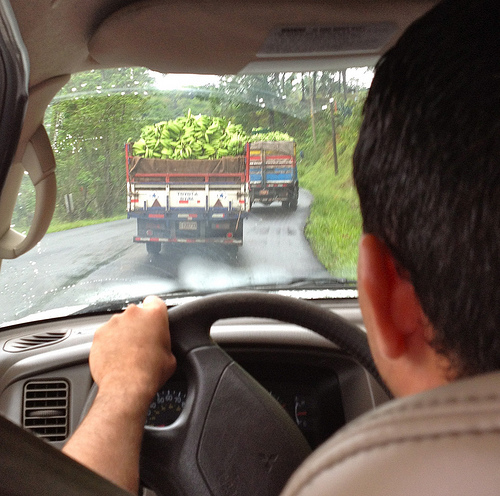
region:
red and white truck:
[119, 153, 282, 256]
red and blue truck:
[237, 130, 297, 185]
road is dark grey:
[240, 210, 285, 270]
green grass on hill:
[283, 151, 365, 268]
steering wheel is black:
[97, 270, 355, 493]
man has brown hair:
[355, 3, 490, 347]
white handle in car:
[0, 120, 75, 275]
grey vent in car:
[13, 365, 89, 452]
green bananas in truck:
[132, 105, 230, 174]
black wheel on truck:
[131, 212, 168, 262]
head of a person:
[328, 15, 499, 389]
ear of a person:
[354, 222, 425, 349]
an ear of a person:
[330, 230, 437, 360]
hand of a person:
[85, 275, 208, 387]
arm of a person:
[65, 385, 135, 482]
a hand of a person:
[85, 297, 194, 389]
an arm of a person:
[45, 398, 199, 486]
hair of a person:
[399, 95, 496, 216]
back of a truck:
[108, 207, 242, 264]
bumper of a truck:
[125, 219, 254, 261]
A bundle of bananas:
[134, 116, 241, 156]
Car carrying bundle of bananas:
[126, 115, 247, 256]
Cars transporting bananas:
[121, 111, 299, 258]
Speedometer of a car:
[136, 385, 189, 430]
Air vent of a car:
[21, 373, 76, 441]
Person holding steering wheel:
[61, 286, 393, 493]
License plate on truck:
[177, 223, 201, 233]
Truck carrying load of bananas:
[124, 113, 251, 253]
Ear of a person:
[353, 237, 415, 356]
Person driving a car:
[68, 25, 485, 491]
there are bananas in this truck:
[113, 104, 274, 261]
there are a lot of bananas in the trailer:
[120, 102, 260, 252]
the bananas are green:
[101, 68, 269, 251]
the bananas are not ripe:
[118, 85, 263, 269]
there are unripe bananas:
[101, 97, 279, 255]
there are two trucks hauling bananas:
[102, 83, 325, 257]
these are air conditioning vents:
[12, 317, 99, 450]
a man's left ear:
[342, 208, 429, 365]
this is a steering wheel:
[64, 260, 376, 492]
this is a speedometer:
[142, 371, 189, 425]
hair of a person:
[371, 73, 461, 180]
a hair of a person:
[393, 56, 468, 187]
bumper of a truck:
[140, 192, 239, 247]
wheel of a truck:
[139, 238, 179, 264]